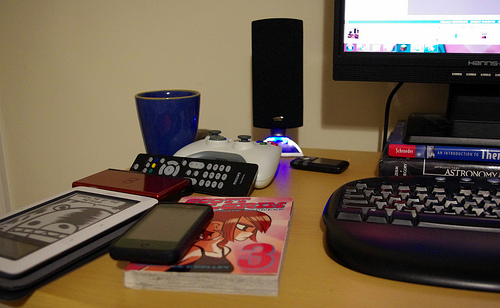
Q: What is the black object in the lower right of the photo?
A: Keyboard.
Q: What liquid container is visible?
A: Blue cup.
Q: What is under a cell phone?
A: A pink book.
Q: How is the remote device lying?
A: At an angle.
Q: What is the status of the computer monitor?
A: On.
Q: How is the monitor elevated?
A: Sitting on books.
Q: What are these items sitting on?
A: Desk.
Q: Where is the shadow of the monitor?
A: On wall.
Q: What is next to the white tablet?
A: A cell phone.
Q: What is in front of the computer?
A: A keyboard.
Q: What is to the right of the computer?
A: A speaker.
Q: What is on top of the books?
A: A computer monitor.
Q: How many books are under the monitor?
A: 2.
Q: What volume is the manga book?
A: Vol 3.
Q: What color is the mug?
A: Blue.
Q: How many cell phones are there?
A: 2.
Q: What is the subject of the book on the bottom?
A: Astronomy.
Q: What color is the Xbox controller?
A: White.